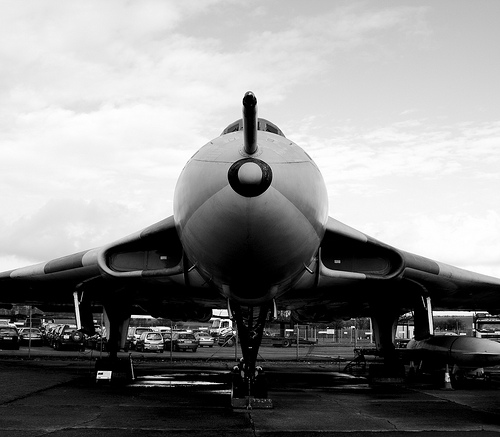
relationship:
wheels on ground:
[202, 365, 295, 398] [22, 360, 451, 433]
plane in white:
[0, 116, 499, 363] [152, 149, 341, 211]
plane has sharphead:
[0, 116, 499, 363] [207, 76, 305, 218]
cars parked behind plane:
[26, 321, 221, 357] [0, 116, 499, 363]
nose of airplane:
[234, 87, 272, 151] [0, 116, 499, 363]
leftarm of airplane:
[10, 235, 189, 314] [0, 116, 499, 363]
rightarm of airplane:
[341, 220, 490, 313] [0, 116, 499, 363]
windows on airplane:
[224, 111, 295, 134] [0, 116, 499, 363]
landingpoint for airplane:
[22, 360, 451, 433] [0, 116, 499, 363]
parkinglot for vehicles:
[5, 321, 369, 363] [142, 323, 198, 351]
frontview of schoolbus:
[435, 313, 482, 339] [391, 313, 490, 336]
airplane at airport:
[0, 116, 499, 363] [8, 240, 496, 434]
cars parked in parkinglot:
[26, 321, 221, 357] [5, 321, 369, 363]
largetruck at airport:
[212, 319, 318, 353] [8, 240, 496, 434]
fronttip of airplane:
[237, 87, 270, 113] [0, 116, 499, 363]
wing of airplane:
[341, 220, 490, 313] [0, 116, 499, 363]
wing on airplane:
[337, 226, 475, 288] [0, 116, 499, 363]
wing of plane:
[337, 226, 475, 288] [0, 116, 499, 363]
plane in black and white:
[0, 116, 499, 363] [2, 2, 499, 369]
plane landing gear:
[0, 116, 499, 363] [216, 340, 317, 408]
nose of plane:
[234, 87, 272, 151] [0, 116, 499, 363]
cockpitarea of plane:
[217, 93, 304, 140] [0, 116, 499, 363]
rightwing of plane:
[341, 220, 490, 313] [0, 116, 499, 363]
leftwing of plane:
[10, 235, 189, 314] [0, 116, 499, 363]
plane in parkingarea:
[0, 116, 499, 363] [22, 360, 451, 433]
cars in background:
[26, 321, 221, 357] [6, 313, 331, 351]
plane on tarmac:
[0, 116, 499, 363] [22, 360, 451, 433]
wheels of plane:
[202, 365, 295, 398] [0, 116, 499, 363]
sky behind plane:
[30, 17, 486, 80] [0, 116, 499, 363]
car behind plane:
[142, 329, 227, 348] [0, 116, 499, 363]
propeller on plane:
[95, 243, 172, 268] [0, 116, 499, 363]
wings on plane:
[341, 220, 490, 313] [0, 116, 499, 363]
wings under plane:
[63, 306, 112, 340] [0, 116, 499, 363]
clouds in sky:
[116, 40, 265, 105] [30, 17, 486, 80]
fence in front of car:
[164, 332, 325, 360] [142, 329, 227, 348]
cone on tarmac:
[436, 365, 459, 391] [67, 397, 462, 422]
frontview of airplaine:
[0, 116, 499, 363] [0, 87, 499, 431]